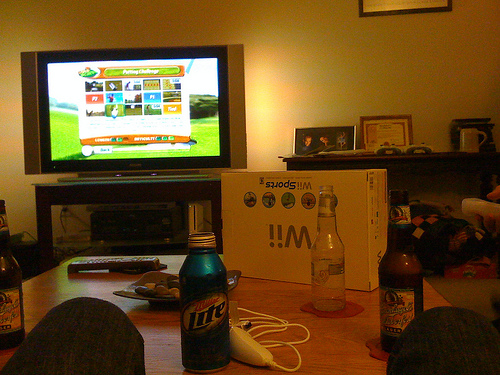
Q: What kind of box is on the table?
A: WII.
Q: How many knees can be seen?
A: Two.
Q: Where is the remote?
A: Table.